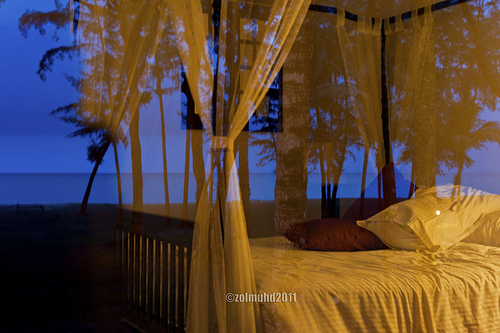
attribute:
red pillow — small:
[335, 165, 414, 234]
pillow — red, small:
[283, 217, 388, 254]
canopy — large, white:
[92, 6, 495, 146]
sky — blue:
[2, 0, 495, 212]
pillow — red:
[261, 210, 386, 254]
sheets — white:
[247, 230, 499, 331]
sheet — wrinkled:
[120, 234, 499, 331]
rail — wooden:
[92, 202, 221, 269]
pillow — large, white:
[352, 186, 492, 256]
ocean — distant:
[0, 174, 497, 199]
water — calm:
[0, 169, 490, 209]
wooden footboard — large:
[108, 202, 195, 329]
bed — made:
[235, 204, 498, 332]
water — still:
[1, 157, 498, 209]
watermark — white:
[221, 288, 300, 308]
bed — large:
[75, 0, 498, 332]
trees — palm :
[41, 56, 366, 230]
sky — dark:
[28, 24, 229, 223]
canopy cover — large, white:
[79, 2, 491, 332]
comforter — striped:
[120, 228, 498, 331]